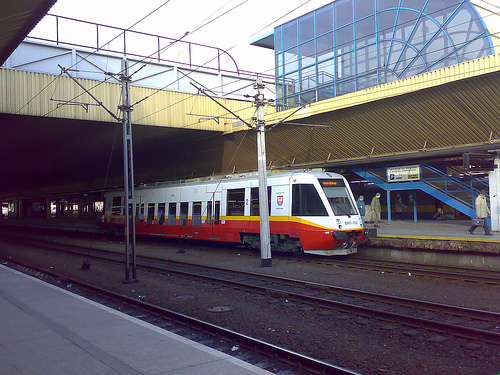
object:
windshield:
[321, 176, 361, 216]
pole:
[257, 134, 270, 268]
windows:
[189, 200, 205, 227]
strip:
[221, 215, 302, 225]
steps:
[446, 188, 477, 210]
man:
[370, 192, 383, 227]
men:
[356, 194, 367, 225]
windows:
[180, 202, 190, 229]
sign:
[321, 180, 338, 187]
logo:
[271, 187, 289, 217]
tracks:
[89, 228, 496, 375]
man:
[468, 190, 492, 236]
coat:
[476, 194, 490, 219]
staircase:
[354, 161, 492, 229]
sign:
[386, 163, 421, 183]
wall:
[263, 0, 490, 134]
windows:
[442, 1, 485, 46]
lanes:
[0, 220, 500, 373]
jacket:
[353, 197, 366, 218]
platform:
[5, 264, 263, 375]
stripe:
[0, 263, 232, 375]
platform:
[366, 217, 498, 239]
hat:
[480, 189, 487, 195]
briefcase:
[471, 218, 485, 228]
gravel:
[208, 294, 369, 341]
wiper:
[328, 199, 352, 218]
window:
[271, 30, 296, 73]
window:
[294, 15, 314, 64]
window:
[332, 0, 354, 47]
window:
[306, 3, 335, 35]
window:
[356, 2, 378, 21]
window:
[369, 8, 392, 39]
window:
[314, 36, 335, 66]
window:
[281, 51, 301, 74]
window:
[280, 69, 300, 96]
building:
[249, 0, 500, 233]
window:
[337, 56, 358, 85]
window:
[318, 182, 358, 220]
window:
[290, 181, 328, 221]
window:
[251, 185, 272, 215]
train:
[5, 161, 365, 264]